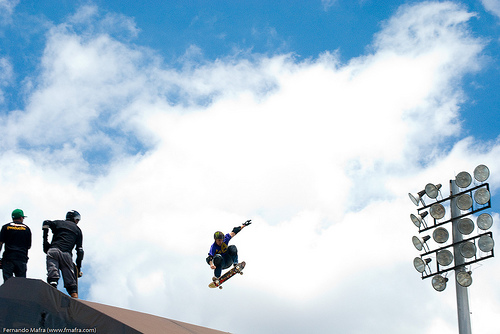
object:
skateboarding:
[205, 217, 256, 288]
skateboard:
[208, 261, 248, 290]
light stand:
[448, 179, 474, 333]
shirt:
[3, 222, 34, 260]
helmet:
[65, 209, 82, 221]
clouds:
[0, 0, 499, 334]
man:
[204, 217, 255, 283]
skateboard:
[72, 261, 78, 279]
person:
[6, 207, 33, 292]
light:
[406, 190, 427, 209]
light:
[424, 182, 443, 200]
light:
[455, 171, 473, 192]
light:
[473, 163, 491, 185]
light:
[432, 227, 449, 246]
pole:
[441, 170, 476, 332]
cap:
[10, 208, 29, 219]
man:
[42, 209, 85, 298]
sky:
[4, 3, 496, 333]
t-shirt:
[208, 233, 234, 263]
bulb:
[477, 168, 485, 177]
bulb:
[481, 240, 491, 248]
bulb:
[432, 278, 442, 286]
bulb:
[414, 241, 421, 247]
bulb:
[437, 232, 444, 238]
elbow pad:
[231, 226, 242, 235]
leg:
[212, 254, 226, 277]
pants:
[0, 257, 28, 280]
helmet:
[213, 231, 225, 239]